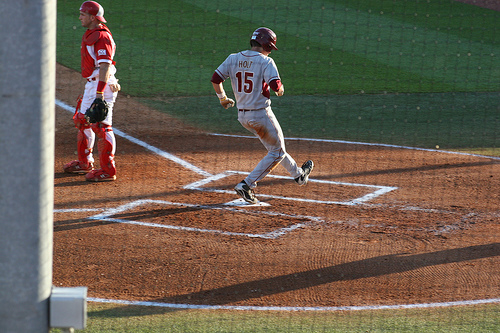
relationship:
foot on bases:
[231, 175, 258, 203] [218, 188, 275, 212]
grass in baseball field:
[55, 0, 495, 149] [57, 0, 496, 329]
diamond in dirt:
[59, 47, 494, 328] [141, 245, 329, 288]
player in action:
[209, 24, 316, 204] [48, 11, 428, 297]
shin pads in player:
[69, 108, 128, 200] [67, 4, 129, 184]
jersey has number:
[212, 53, 282, 108] [233, 69, 254, 94]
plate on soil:
[223, 196, 278, 208] [53, 128, 497, 330]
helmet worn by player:
[247, 23, 281, 55] [208, 22, 317, 204]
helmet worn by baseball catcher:
[71, 1, 117, 25] [63, 0, 121, 181]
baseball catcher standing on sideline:
[63, 0, 128, 178] [55, 94, 215, 179]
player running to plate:
[217, 24, 314, 206] [226, 193, 271, 208]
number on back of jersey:
[231, 70, 255, 96] [210, 53, 282, 111]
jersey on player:
[210, 53, 282, 111] [208, 22, 317, 204]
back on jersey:
[230, 51, 269, 108] [210, 53, 282, 111]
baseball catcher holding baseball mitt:
[63, 0, 121, 181] [86, 97, 107, 127]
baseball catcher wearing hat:
[63, 0, 121, 181] [78, 0, 112, 25]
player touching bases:
[209, 24, 316, 204] [222, 194, 273, 208]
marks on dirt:
[57, 95, 495, 313] [53, 134, 499, 288]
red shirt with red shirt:
[78, 27, 115, 79] [78, 27, 115, 79]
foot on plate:
[231, 181, 258, 203] [223, 196, 278, 208]